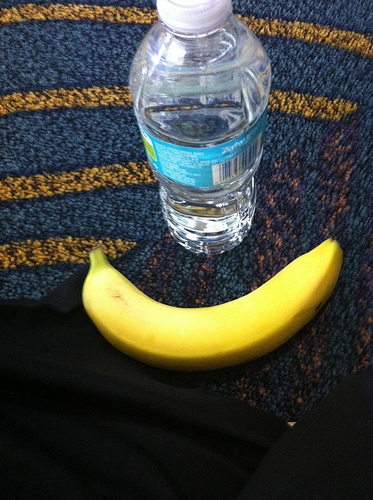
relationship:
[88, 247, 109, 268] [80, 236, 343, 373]
tip of banana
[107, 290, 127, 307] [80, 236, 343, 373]
bruise on banana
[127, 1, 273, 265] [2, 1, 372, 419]
bottle on carpet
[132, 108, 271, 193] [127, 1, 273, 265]
label on bottle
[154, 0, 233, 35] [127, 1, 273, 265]
cap of bottle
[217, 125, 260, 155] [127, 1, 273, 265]
zephyrhills on bottle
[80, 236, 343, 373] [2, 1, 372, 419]
banana on carpet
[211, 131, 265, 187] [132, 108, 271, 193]
barcode on label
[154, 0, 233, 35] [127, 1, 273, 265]
cap on bottle